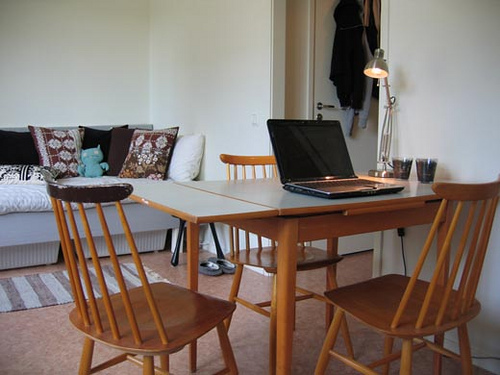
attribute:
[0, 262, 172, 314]
runner — blue, gray, striped, rug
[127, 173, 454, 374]
table — wood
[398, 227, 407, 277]
electrical cord — black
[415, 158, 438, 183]
cup — black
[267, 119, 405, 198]
lap top — black, open, off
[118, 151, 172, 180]
pillow — brown, floral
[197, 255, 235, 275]
slipper — gray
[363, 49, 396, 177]
table lamp — silver, metal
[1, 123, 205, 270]
couch — gray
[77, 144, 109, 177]
stuffed animal — blue, light blue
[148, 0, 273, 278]
wall — white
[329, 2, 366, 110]
sweatshirt — hanging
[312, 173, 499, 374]
chair — wooden